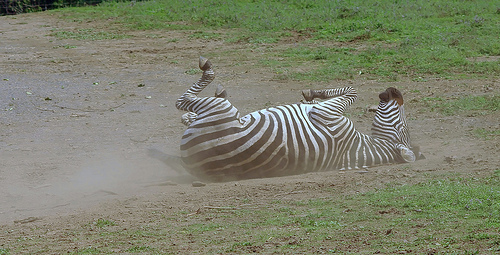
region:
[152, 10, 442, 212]
zebra laying on its back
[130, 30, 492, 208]
zebra rolling in the dirt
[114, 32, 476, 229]
zebra looking up towards the sky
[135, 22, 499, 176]
zebra with his hooves in the air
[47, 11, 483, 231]
a land with dirt and grass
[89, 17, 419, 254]
a zebra enjoy the day light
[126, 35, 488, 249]
black and white zebra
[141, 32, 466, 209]
a black and white zebra on its back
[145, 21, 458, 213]
a black and white zebra rolling on its back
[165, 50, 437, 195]
a zebra on its back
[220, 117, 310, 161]
the zebra has stripes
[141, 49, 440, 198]
the zebra rolls in the dirt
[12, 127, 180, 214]
the dirt is dry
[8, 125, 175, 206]
the dirt is brown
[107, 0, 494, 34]
the grass is green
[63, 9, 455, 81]
the grass is patchy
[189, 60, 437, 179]
the zebra is black and white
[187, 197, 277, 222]
a stick on the ground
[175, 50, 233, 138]
the zebras leg is bent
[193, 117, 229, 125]
The black strip of the zebra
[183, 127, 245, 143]
The black strip of the zebra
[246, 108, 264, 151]
The black strip of the zebra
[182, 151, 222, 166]
The black strip of the zebra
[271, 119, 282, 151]
The black strip of the zebra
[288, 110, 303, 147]
The black strip of the zebra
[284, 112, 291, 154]
The black strip of the zebra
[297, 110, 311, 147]
The black strip of the zebra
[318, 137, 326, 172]
The black strip of the zebra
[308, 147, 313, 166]
The black strip of the zebra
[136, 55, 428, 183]
a zebra is upside down in the dirt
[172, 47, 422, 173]
the zebra's legs are in the air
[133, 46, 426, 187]
the zebra is scratching his back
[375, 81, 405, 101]
the zebra has a black nose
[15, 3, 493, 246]
green grass is growing on the hill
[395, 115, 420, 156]
the zebra's eyes are closed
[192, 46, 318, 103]
the zebra's hooves are in the air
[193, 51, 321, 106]
the hooves are gray and black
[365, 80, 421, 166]
the head of the zebra is straight up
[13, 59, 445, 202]
the zebra is raising dust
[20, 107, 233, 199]
Dust is in the air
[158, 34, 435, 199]
The animal in this picture is a zebra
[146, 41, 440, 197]
Zebra is on the ground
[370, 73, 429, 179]
Zebra's face is pointing up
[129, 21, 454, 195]
A side view of a zebra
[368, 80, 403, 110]
Zebra's nose is black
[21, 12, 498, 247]
Photo was taken in the daytime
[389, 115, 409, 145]
Zebra's eyes are closed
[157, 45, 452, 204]
Zebra's body is pointing upward on the ground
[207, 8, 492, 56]
Grass is in the background